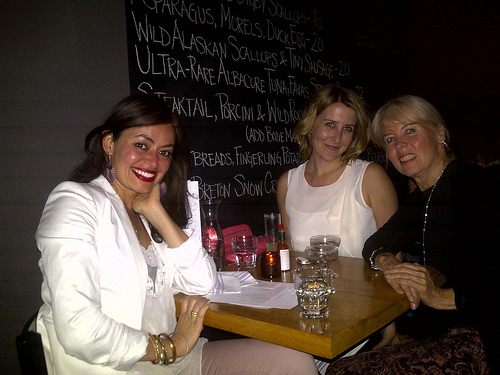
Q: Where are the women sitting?
A: Around a table.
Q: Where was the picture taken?
A: At a restaurant.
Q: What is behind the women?
A: A blackboard with a menu.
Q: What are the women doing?
A: Smiling for the camera.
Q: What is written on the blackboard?
A: A menu.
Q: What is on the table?
A: Glass cups.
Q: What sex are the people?
A: Female.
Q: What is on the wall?
A: Blackboard.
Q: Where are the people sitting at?
A: A table.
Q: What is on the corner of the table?
A: Glass.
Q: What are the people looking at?
A: The camera.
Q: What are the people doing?
A: Sitting.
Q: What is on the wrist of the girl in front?
A: Bracelets.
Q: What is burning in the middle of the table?
A: Candle.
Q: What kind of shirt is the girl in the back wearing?
A: Tank top.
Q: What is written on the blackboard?
A: Food items.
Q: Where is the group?
A: At a table.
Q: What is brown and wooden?
A: Table.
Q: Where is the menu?
A: On the wall.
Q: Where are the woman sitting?
A: At the table.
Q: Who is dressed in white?
A: A woman.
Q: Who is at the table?
A: Three women.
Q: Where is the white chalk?
A: On the black board.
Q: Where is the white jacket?
A: On the woman.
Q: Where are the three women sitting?
A: At the table.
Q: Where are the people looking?
A: At the camera.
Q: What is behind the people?
A: A menu.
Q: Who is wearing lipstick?
A: The woman on the left.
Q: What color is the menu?
A: Black.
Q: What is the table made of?
A: Wood.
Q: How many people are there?
A: Three.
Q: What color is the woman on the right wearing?
A: Black.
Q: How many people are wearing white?
A: Two.